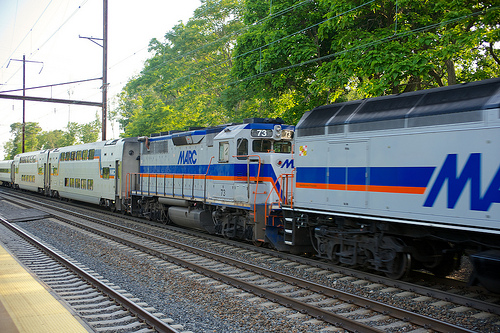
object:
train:
[0, 78, 499, 280]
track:
[0, 179, 499, 332]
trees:
[111, 3, 489, 140]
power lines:
[21, 6, 104, 61]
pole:
[101, 1, 107, 140]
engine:
[127, 120, 288, 248]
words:
[173, 151, 196, 165]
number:
[255, 127, 268, 138]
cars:
[12, 137, 140, 212]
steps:
[256, 171, 302, 253]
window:
[216, 141, 230, 166]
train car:
[288, 78, 500, 279]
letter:
[423, 152, 481, 213]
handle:
[262, 175, 283, 204]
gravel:
[0, 199, 499, 331]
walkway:
[124, 169, 219, 205]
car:
[12, 150, 47, 199]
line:
[287, 161, 438, 186]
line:
[296, 182, 428, 198]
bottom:
[260, 193, 499, 289]